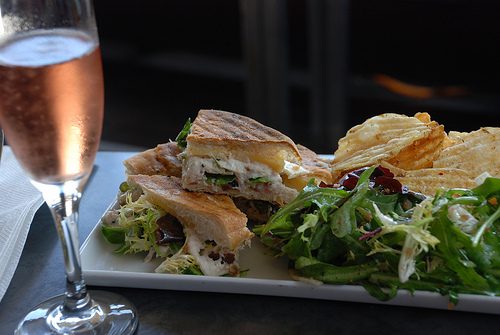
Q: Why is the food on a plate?
A: It is being served.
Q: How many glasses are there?
A: One.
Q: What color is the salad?
A: Green.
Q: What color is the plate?
A: White.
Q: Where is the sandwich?
A: On the plate.